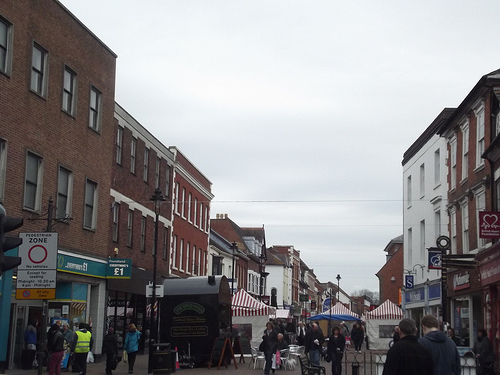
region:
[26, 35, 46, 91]
third story single window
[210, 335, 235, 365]
black advertising sign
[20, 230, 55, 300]
white parking sign with black lettering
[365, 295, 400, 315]
read and white striped tent roof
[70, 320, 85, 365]
man in yellow vest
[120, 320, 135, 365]
woman with blue coat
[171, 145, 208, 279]
three story red brink building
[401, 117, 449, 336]
three story white building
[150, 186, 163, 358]
thin black street light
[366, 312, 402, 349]
white tent with clear window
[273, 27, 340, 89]
part of a cloud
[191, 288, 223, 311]
edge of a can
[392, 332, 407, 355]
edge of a collar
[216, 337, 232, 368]
part of a stand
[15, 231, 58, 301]
a pedestrian zone street sign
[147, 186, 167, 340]
a street lamp and post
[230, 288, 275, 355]
an arts and craft tent booth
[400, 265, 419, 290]
store business name banners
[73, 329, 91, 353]
a man wearing a fluorescent yellow safety vest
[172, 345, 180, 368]
an orange safety cone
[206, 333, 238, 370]
a menu sidewalk display board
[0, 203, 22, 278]
a traffic light at the corner of the street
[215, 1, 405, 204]
grey sky with grey clouds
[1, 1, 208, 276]
brick buildings on the side of the road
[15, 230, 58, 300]
a sign on the side of the street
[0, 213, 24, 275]
a black traffic light at the intersection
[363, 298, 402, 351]
a tent booth for arts and craft shows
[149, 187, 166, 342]
a street light lamp post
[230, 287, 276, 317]
a red and white striped tent canopy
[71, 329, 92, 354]
a fluorescent yellow safety vest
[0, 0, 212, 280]
red brick buildings on the side of the road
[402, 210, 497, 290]
store signs at the entrance to the shops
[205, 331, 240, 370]
a menu sidewalk sign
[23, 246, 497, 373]
people in a busy street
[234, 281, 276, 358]
white tents in the street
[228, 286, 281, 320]
roof of tents are white and red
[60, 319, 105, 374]
person wearing a green vest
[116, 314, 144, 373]
woman wearing a long blue sleeve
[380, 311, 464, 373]
a couple walking in the street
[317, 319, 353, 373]
woman wearing black suit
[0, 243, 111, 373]
people in front of store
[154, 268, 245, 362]
a black cabin on side of street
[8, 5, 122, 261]
building of brick